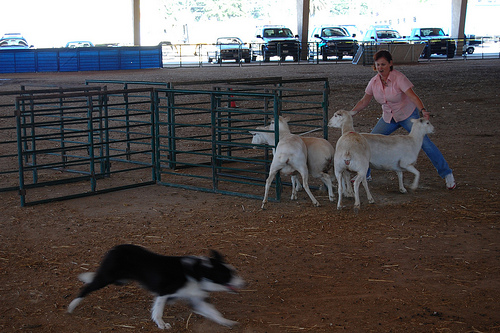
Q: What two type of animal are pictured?
A: Sheep and a dog.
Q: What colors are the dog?
A: Black and white.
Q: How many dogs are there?
A: One.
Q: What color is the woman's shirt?
A: Pink.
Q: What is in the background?
A: Parked cars.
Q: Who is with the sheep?
A: The woman.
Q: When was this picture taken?
A: Daytime.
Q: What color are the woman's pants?
A: Blue.